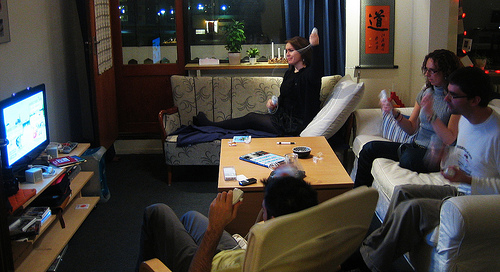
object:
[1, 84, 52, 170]
game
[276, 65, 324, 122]
sweater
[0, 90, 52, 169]
wii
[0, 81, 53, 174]
lcd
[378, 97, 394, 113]
hand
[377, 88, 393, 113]
remote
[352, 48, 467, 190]
woman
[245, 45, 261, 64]
plant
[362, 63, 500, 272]
man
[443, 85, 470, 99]
glasses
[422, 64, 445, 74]
glasses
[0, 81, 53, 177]
computer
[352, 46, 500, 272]
two people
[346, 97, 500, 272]
couch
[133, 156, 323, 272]
guy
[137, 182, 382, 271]
chair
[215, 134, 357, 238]
table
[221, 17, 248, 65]
plant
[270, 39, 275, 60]
candles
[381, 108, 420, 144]
pillow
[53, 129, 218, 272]
carpet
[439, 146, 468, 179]
controller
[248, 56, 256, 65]
pot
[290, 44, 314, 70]
arm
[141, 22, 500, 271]
game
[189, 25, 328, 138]
girl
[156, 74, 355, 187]
sofa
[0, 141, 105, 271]
console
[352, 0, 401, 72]
art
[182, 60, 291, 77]
counter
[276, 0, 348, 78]
curtain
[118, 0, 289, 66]
window